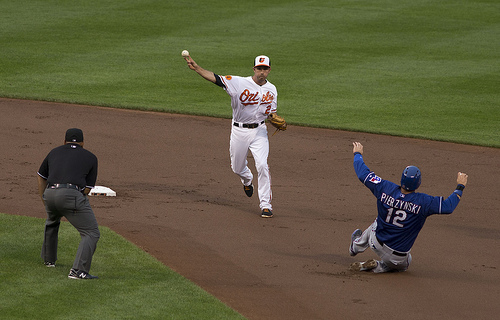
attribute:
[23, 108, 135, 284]
umpire — here, hunched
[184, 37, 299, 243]
player — throwing, here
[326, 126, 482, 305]
player — sliding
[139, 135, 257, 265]
dirt — brown, here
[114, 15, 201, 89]
grass — green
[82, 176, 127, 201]
base — white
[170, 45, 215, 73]
ball — here, thrown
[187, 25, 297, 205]
uniform — white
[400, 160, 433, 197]
helmet — blue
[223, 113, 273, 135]
belt — black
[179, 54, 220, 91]
arm — air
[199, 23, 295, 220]
man — here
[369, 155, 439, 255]
uniform — blue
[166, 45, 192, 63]
baseball — thrown, here, white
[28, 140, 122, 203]
shirt — black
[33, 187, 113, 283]
pants — grey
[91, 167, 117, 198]
plate — baseball, here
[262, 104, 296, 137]
glove — brown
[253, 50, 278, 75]
cap — orange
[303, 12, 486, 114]
outfield — grassy